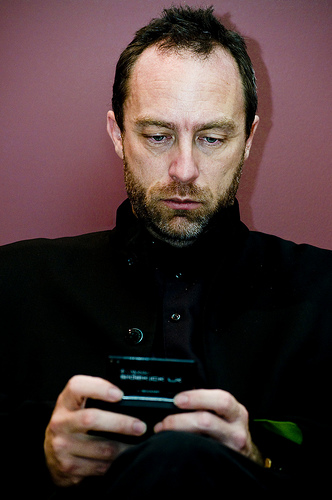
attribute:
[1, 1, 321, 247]
wall — burgundy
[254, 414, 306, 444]
lining — green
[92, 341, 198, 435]
device — electronic 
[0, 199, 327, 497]
coat — black 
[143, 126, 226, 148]
eyes — blue 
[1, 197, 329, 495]
jacket — black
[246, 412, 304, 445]
pocket liner — green 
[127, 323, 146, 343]
light — blue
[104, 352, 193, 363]
light — blue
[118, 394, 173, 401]
light — blue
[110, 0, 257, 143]
hair — brown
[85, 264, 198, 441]
phone — black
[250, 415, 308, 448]
fabric — green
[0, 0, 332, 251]
walls — mauve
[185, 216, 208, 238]
patch — grey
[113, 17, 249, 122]
hairline — receding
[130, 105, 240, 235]
expression — serious